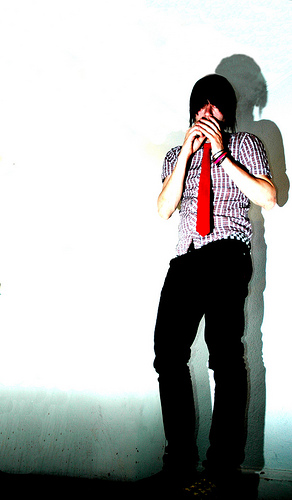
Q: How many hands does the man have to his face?
A: 2.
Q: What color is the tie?
A: Red.